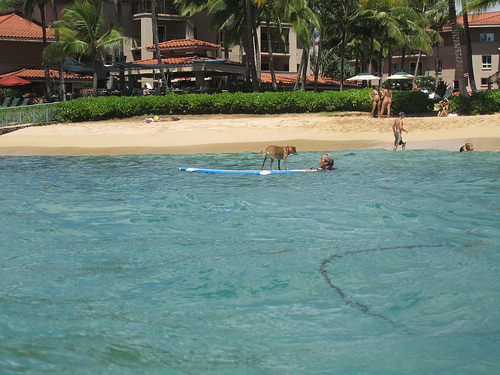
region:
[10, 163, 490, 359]
the ocean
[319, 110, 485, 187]
people in the water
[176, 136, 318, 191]
a dog on a surfboard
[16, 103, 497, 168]
a beach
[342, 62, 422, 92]
a couple of umbrellas at the beach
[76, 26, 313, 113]
a beach house near the shore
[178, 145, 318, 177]
small dog on a surfboard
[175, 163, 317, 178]
blue and white surfboard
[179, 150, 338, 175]
man next to a surfboard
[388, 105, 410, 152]
man walking on a beach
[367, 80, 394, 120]
two women wearing bikinis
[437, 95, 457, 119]
woman wearing a bikini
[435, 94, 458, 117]
woman sitting on a towel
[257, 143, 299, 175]
brown dog with red collar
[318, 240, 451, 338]
black line under the water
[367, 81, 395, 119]
women talking on a beach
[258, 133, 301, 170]
a dog on a surf board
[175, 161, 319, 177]
blue surf board with white stripes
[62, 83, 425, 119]
bushes along the sand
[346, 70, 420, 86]
white umbrellas under the trees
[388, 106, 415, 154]
person steps out of the water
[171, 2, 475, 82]
tall palm trees past the bushes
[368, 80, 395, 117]
girls in swim suits talking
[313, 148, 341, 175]
a head with blond hair above the water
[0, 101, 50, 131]
a metal fence next to the bushes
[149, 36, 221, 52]
terra cotta tiled roof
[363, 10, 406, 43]
green leaf on tree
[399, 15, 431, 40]
green leaf on tree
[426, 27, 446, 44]
green leaf on tree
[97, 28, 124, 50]
green leaf on tree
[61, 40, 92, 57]
green leaf on tree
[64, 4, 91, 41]
green leaf on tree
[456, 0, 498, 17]
green leaf on tree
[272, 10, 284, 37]
green leaf on tree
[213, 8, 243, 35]
green leaf on tree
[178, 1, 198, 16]
green leaf on tree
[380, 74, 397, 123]
woman wearing a bikini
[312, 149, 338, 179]
man swimming in the water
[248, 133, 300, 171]
dog on a surfboard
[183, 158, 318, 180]
blue and white surfboard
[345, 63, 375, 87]
green and white umbrella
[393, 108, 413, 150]
man walking along the beach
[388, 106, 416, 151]
man wearing a baseball cap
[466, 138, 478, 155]
child swimming in the water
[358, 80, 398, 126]
tow women having a conversation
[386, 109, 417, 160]
man with no shirt on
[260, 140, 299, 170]
brown dog on surf board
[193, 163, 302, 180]
blue surf board in water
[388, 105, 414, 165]
man walking in blue water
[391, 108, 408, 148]
person in grey shorts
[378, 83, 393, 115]
woman standing on the beach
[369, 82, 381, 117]
woman standing on the beach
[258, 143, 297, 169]
yellow dog with a red collar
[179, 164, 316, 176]
blue and white surfboard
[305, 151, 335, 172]
person holding onto the surfboard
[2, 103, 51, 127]
grey fence near the shrubs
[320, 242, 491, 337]
black ring in the water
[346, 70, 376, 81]
white and blue umbrella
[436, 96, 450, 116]
woman sitting in the sand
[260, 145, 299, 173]
dog standing on surfboard